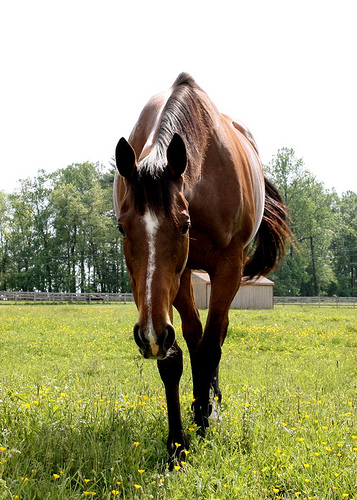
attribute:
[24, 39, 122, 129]
clouds — white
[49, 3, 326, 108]
sky — blue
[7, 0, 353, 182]
clouds — white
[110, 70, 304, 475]
horse — walking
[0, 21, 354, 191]
clouds — white 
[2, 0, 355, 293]
sky — blue , white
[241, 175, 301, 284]
tail — horse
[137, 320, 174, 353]
nostrils — large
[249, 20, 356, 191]
clouds — white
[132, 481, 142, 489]
flower — small, yellow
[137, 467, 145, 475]
flower — small, yellow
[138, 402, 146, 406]
flower — small, yellow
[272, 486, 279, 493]
flower — small, yellow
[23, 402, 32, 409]
flower — small, yellow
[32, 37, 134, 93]
clouds — white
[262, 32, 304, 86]
clouds — white 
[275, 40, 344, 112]
clouds — white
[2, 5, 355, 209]
sky — blue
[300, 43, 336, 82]
clouds — white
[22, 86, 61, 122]
clouds — white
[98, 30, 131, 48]
clouds — white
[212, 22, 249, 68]
clouds — white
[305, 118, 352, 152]
clouds — white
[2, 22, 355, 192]
sky —  blue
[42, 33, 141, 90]
clouds — white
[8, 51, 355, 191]
sky — blue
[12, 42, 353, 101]
sky — blue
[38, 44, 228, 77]
clouds — white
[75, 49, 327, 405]
horse — brown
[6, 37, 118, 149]
sky — blue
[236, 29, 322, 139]
sky — blue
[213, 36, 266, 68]
clouds — white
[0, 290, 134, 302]
fencing — wooden 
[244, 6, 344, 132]
clouds — white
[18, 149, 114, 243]
clouds — white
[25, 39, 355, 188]
sky — blue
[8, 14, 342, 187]
sky — blue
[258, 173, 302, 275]
hair — long, brown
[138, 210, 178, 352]
stripe — white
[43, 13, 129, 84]
clouds — white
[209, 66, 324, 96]
clouds — white